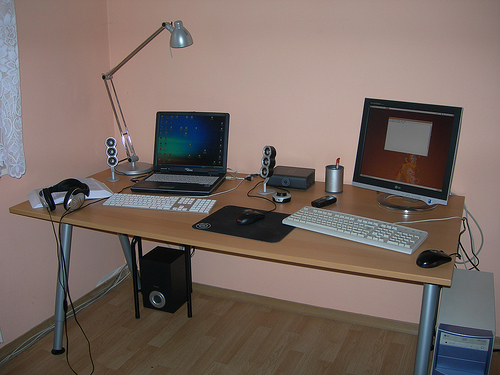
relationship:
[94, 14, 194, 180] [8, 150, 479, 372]
lamp on table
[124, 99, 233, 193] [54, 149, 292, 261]
laptop on table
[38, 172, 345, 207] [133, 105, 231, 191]
computer equpment has computer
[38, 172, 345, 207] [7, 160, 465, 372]
computer equpment on desk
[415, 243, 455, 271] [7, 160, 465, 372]
computer mouse on desk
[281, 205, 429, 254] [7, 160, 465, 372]
keyboard on desk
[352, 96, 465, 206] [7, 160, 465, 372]
computer on desk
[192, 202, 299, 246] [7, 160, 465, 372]
mouse pad on desk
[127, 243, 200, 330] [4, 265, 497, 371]
speaker sitting on floor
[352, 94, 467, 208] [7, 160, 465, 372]
screen on desk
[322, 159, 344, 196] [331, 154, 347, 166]
can with pens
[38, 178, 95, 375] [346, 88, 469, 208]
earphones in front of computer monitor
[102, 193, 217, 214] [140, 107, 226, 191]
computer equpment in front of laptop.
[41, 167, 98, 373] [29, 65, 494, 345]
earphones are on table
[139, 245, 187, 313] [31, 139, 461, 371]
speaker under table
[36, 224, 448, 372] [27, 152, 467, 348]
legs on table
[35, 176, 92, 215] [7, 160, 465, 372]
head phones on desk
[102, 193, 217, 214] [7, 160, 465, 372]
computer equpment on desk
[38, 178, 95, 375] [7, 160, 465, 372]
earphones on desk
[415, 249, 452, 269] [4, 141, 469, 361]
computer mouse on desk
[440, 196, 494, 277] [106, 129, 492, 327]
wires hanging from desk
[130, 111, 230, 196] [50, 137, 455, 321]
computer on desk